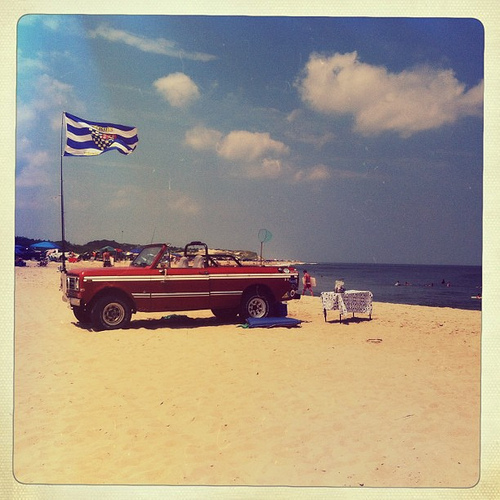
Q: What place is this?
A: It is a beach.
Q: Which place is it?
A: It is a beach.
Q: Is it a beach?
A: Yes, it is a beach.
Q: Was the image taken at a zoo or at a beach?
A: It was taken at a beach.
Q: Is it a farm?
A: No, it is a beach.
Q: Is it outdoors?
A: Yes, it is outdoors.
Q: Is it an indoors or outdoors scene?
A: It is outdoors.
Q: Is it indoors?
A: No, it is outdoors.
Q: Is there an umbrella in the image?
A: Yes, there is an umbrella.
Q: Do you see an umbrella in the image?
A: Yes, there is an umbrella.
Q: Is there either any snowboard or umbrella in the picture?
A: Yes, there is an umbrella.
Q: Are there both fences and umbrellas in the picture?
A: No, there is an umbrella but no fences.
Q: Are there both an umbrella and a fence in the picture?
A: No, there is an umbrella but no fences.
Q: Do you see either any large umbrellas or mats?
A: Yes, there is a large umbrella.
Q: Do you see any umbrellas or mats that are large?
A: Yes, the umbrella is large.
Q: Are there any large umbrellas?
A: Yes, there is a large umbrella.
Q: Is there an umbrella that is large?
A: Yes, there is an umbrella that is large.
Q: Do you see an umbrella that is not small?
A: Yes, there is a large umbrella.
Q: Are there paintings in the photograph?
A: No, there are no paintings.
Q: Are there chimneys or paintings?
A: No, there are no paintings or chimneys.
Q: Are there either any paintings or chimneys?
A: No, there are no paintings or chimneys.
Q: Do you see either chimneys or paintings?
A: No, there are no paintings or chimneys.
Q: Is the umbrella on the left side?
A: Yes, the umbrella is on the left of the image.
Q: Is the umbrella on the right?
A: No, the umbrella is on the left of the image.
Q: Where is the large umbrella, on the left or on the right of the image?
A: The umbrella is on the left of the image.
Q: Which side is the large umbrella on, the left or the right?
A: The umbrella is on the left of the image.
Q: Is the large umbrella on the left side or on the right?
A: The umbrella is on the left of the image.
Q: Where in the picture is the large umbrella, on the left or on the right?
A: The umbrella is on the left of the image.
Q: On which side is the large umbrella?
A: The umbrella is on the left of the image.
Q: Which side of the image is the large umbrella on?
A: The umbrella is on the left of the image.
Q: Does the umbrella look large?
A: Yes, the umbrella is large.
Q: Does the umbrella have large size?
A: Yes, the umbrella is large.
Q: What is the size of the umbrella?
A: The umbrella is large.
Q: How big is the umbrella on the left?
A: The umbrella is large.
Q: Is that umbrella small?
A: No, the umbrella is large.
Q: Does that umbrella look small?
A: No, the umbrella is large.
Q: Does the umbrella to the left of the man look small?
A: No, the umbrella is large.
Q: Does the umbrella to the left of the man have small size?
A: No, the umbrella is large.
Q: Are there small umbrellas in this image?
A: No, there is an umbrella but it is large.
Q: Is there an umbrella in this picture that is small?
A: No, there is an umbrella but it is large.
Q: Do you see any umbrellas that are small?
A: No, there is an umbrella but it is large.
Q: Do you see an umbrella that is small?
A: No, there is an umbrella but it is large.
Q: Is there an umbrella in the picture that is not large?
A: No, there is an umbrella but it is large.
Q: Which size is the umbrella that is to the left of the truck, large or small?
A: The umbrella is large.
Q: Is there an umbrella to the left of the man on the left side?
A: Yes, there is an umbrella to the left of the man.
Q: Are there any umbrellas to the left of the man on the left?
A: Yes, there is an umbrella to the left of the man.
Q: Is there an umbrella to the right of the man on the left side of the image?
A: No, the umbrella is to the left of the man.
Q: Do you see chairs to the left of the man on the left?
A: No, there is an umbrella to the left of the man.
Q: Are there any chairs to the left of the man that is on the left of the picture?
A: No, there is an umbrella to the left of the man.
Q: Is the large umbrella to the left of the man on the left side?
A: Yes, the umbrella is to the left of the man.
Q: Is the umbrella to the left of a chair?
A: No, the umbrella is to the left of the man.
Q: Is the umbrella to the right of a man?
A: No, the umbrella is to the left of a man.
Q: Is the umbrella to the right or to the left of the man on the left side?
A: The umbrella is to the left of the man.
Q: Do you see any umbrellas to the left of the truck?
A: Yes, there is an umbrella to the left of the truck.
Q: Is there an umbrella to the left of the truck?
A: Yes, there is an umbrella to the left of the truck.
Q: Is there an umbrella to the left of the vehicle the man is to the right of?
A: Yes, there is an umbrella to the left of the truck.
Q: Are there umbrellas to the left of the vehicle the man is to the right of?
A: Yes, there is an umbrella to the left of the truck.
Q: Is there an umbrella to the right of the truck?
A: No, the umbrella is to the left of the truck.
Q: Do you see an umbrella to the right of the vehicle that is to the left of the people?
A: No, the umbrella is to the left of the truck.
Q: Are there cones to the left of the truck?
A: No, there is an umbrella to the left of the truck.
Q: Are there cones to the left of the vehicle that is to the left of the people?
A: No, there is an umbrella to the left of the truck.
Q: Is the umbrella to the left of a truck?
A: Yes, the umbrella is to the left of a truck.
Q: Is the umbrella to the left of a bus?
A: No, the umbrella is to the left of a truck.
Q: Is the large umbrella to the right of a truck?
A: No, the umbrella is to the left of a truck.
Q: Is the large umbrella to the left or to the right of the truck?
A: The umbrella is to the left of the truck.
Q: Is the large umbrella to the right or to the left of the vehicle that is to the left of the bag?
A: The umbrella is to the left of the truck.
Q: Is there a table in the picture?
A: Yes, there is a table.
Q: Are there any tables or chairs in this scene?
A: Yes, there is a table.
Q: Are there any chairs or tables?
A: Yes, there is a table.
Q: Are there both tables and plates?
A: No, there is a table but no plates.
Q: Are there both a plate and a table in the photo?
A: No, there is a table but no plates.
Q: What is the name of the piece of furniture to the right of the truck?
A: The piece of furniture is a table.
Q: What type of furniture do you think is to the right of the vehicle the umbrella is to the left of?
A: The piece of furniture is a table.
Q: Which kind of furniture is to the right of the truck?
A: The piece of furniture is a table.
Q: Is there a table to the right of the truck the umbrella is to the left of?
A: Yes, there is a table to the right of the truck.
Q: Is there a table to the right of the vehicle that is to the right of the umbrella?
A: Yes, there is a table to the right of the truck.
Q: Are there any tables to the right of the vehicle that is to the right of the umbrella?
A: Yes, there is a table to the right of the truck.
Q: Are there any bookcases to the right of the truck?
A: No, there is a table to the right of the truck.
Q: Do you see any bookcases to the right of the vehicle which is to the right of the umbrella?
A: No, there is a table to the right of the truck.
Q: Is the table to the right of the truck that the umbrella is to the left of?
A: Yes, the table is to the right of the truck.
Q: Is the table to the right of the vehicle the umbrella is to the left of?
A: Yes, the table is to the right of the truck.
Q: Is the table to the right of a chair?
A: No, the table is to the right of the truck.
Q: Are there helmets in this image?
A: No, there are no helmets.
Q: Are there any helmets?
A: No, there are no helmets.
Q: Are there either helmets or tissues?
A: No, there are no helmets or tissues.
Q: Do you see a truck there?
A: Yes, there is a truck.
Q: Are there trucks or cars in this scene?
A: Yes, there is a truck.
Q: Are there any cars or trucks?
A: Yes, there is a truck.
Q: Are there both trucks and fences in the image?
A: No, there is a truck but no fences.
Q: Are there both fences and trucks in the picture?
A: No, there is a truck but no fences.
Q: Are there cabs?
A: No, there are no cabs.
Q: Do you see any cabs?
A: No, there are no cabs.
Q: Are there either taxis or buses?
A: No, there are no taxis or buses.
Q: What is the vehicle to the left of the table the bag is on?
A: The vehicle is a truck.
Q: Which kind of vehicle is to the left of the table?
A: The vehicle is a truck.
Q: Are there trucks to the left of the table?
A: Yes, there is a truck to the left of the table.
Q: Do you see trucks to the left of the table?
A: Yes, there is a truck to the left of the table.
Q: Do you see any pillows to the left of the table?
A: No, there is a truck to the left of the table.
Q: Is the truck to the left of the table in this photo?
A: Yes, the truck is to the left of the table.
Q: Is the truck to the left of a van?
A: No, the truck is to the left of the table.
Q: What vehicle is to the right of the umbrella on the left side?
A: The vehicle is a truck.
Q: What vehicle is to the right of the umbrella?
A: The vehicle is a truck.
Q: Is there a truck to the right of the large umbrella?
A: Yes, there is a truck to the right of the umbrella.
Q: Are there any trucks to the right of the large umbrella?
A: Yes, there is a truck to the right of the umbrella.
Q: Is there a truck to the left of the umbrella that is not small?
A: No, the truck is to the right of the umbrella.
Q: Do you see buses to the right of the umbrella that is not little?
A: No, there is a truck to the right of the umbrella.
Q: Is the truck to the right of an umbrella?
A: Yes, the truck is to the right of an umbrella.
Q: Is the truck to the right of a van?
A: No, the truck is to the right of an umbrella.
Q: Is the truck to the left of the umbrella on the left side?
A: No, the truck is to the right of the umbrella.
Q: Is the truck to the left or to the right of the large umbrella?
A: The truck is to the right of the umbrella.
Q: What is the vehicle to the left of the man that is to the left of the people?
A: The vehicle is a truck.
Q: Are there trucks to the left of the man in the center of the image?
A: Yes, there is a truck to the left of the man.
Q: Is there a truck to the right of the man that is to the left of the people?
A: No, the truck is to the left of the man.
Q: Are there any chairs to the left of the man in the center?
A: No, there is a truck to the left of the man.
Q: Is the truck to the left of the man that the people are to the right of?
A: Yes, the truck is to the left of the man.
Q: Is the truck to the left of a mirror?
A: No, the truck is to the left of the man.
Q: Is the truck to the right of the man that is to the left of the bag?
A: No, the truck is to the left of the man.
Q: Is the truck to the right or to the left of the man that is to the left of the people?
A: The truck is to the left of the man.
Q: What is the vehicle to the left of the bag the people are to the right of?
A: The vehicle is a truck.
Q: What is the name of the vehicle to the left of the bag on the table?
A: The vehicle is a truck.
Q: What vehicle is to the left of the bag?
A: The vehicle is a truck.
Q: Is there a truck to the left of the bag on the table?
A: Yes, there is a truck to the left of the bag.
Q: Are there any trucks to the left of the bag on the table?
A: Yes, there is a truck to the left of the bag.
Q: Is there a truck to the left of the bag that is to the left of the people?
A: Yes, there is a truck to the left of the bag.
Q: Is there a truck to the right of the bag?
A: No, the truck is to the left of the bag.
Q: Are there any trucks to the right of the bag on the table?
A: No, the truck is to the left of the bag.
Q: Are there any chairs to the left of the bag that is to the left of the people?
A: No, there is a truck to the left of the bag.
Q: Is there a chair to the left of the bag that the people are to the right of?
A: No, there is a truck to the left of the bag.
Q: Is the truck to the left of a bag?
A: Yes, the truck is to the left of a bag.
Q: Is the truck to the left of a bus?
A: No, the truck is to the left of a bag.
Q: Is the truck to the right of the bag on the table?
A: No, the truck is to the left of the bag.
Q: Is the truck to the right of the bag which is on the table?
A: No, the truck is to the left of the bag.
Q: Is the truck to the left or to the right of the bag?
A: The truck is to the left of the bag.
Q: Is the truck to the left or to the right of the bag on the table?
A: The truck is to the left of the bag.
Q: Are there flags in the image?
A: Yes, there is a flag.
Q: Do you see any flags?
A: Yes, there is a flag.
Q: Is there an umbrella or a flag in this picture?
A: Yes, there is a flag.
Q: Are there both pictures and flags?
A: No, there is a flag but no pictures.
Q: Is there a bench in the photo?
A: No, there are no benches.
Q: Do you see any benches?
A: No, there are no benches.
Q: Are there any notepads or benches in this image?
A: No, there are no benches or notepads.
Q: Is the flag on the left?
A: Yes, the flag is on the left of the image.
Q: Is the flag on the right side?
A: No, the flag is on the left of the image.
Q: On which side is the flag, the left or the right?
A: The flag is on the left of the image.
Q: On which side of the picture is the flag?
A: The flag is on the left of the image.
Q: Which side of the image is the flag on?
A: The flag is on the left of the image.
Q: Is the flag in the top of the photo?
A: Yes, the flag is in the top of the image.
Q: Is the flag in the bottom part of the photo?
A: No, the flag is in the top of the image.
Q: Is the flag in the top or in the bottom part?
A: The flag is in the top of the image.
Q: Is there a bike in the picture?
A: No, there are no bikes.